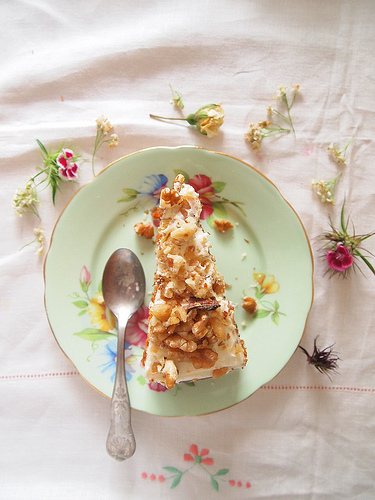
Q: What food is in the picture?
A: A slice of pie.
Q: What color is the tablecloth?
A: White.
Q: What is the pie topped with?
A: Nuts.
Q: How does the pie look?
A: Delicious.